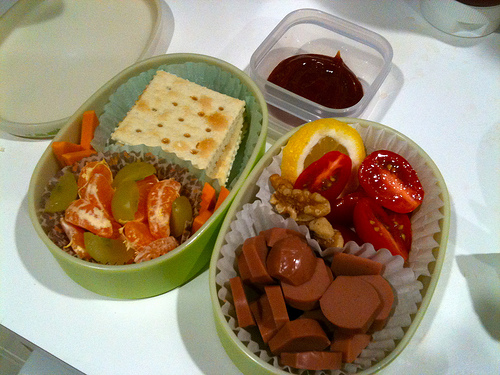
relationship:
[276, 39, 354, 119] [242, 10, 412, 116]
ketchup in container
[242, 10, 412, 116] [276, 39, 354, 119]
container has ketchup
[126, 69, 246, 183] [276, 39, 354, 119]
crackers close to ketchup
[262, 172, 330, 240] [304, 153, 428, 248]
nuts beside tomatoes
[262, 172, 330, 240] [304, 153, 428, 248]
nuts close to tomatoes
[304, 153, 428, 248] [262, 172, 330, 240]
tomatoes close to nuts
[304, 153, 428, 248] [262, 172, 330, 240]
tomatoes near nuts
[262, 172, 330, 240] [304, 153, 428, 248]
nuts near tomatoes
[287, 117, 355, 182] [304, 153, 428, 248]
lemon near tomatoes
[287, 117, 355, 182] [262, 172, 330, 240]
lemon next to nuts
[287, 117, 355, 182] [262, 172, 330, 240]
lemon near nuts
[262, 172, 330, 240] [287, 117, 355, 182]
nuts near lemon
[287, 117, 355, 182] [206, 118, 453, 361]
lemon in cup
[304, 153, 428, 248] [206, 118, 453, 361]
tomatoes in cup